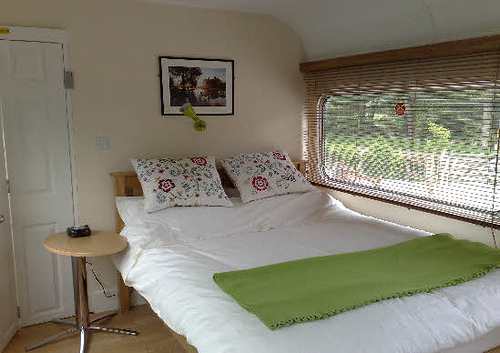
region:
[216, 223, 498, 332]
a green blanket on a bed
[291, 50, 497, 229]
a brown shade covering a window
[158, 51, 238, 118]
a picture hanging on a wall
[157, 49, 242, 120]
a framed picture hanging on a wall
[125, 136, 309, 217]
two pillows on a bed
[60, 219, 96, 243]
a digital clock on a table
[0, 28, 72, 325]
a white closet door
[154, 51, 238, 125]
small white picture frame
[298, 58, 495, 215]
blinds over a window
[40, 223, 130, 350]
rounded tan side table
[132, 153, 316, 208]
two white decorative throw pillows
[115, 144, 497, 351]
a nicely made up bedspread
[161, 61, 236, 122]
a painting of an odl town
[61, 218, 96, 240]
a little black alarm clock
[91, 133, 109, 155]
a lightswitch face plate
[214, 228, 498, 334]
a green blanket on a bed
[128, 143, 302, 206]
two pillows on a bed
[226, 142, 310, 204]
a pillow case with a floral print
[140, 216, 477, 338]
a white bed spread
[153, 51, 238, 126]
a picture in a black frame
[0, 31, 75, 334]
a white door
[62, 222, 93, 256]
a digital clock on a table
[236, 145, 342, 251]
a pillow on bed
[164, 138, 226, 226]
a pillow on bed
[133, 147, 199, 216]
flower on a pillow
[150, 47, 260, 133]
a picture on the wall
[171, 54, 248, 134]
a framed picture on the wall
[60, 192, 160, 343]
a round table next to bed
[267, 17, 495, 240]
blindes on a window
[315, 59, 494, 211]
a window on a wall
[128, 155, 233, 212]
a flower patterned bed pillow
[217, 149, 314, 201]
a flower patterned bed pillow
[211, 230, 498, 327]
a green throw blanket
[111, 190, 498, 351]
a white bed comforter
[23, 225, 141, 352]
a light brown bedside table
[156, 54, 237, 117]
a framed photograph on wall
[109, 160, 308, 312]
a light brown wood headboard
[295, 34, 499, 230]
wooden venetian blinds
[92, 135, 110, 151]
white electrical wall light switch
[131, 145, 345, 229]
the pillows are floral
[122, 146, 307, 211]
the pillows are floral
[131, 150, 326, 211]
the pillows are floral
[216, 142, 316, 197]
A pillow on a bed.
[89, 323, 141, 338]
A leg of a table.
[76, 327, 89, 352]
A leg of a table.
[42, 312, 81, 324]
A leg of a table.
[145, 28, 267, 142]
framed picture on wall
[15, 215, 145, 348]
round side table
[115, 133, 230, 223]
embroidered floral pillow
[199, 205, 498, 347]
green throw blanket on bed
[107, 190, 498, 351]
white comforter on bed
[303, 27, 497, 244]
blinds on window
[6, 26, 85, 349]
white closet door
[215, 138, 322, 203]
floral pillow on bed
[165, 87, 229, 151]
green stuffed toy hanging on picture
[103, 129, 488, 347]
a nicely made bed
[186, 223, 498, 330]
a folded green blanket on a bed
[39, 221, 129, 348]
a small black clock on an end table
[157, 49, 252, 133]
a picture on the wall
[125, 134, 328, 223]
two embroidered flower pillows on a bed